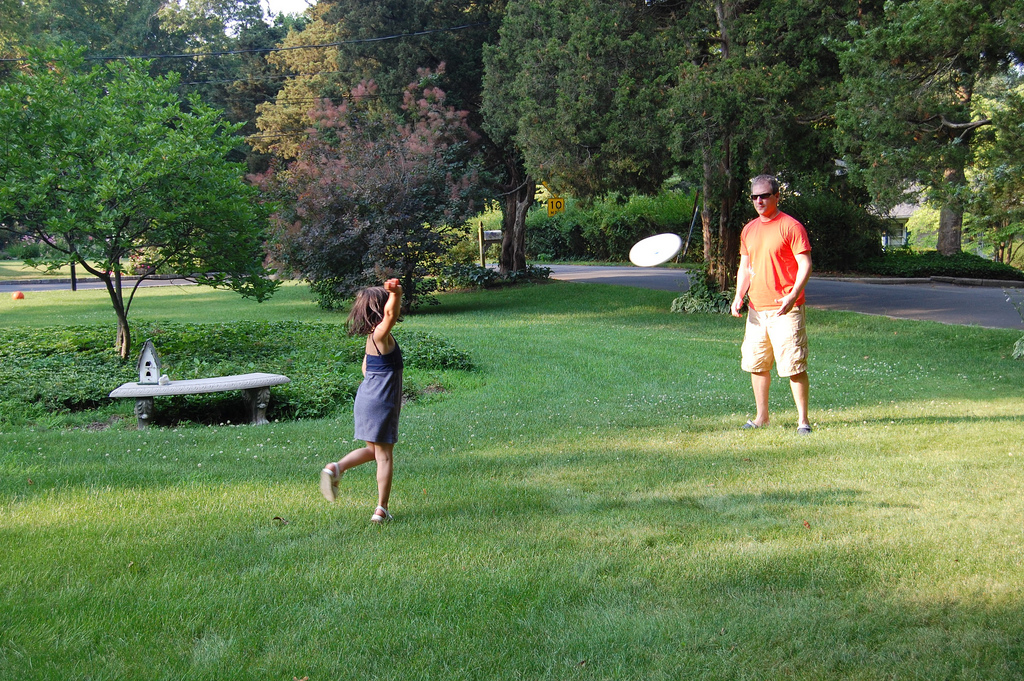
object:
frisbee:
[629, 233, 686, 267]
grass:
[0, 279, 1019, 678]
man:
[731, 175, 813, 433]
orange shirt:
[740, 212, 812, 310]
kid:
[320, 279, 405, 522]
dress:
[353, 333, 404, 443]